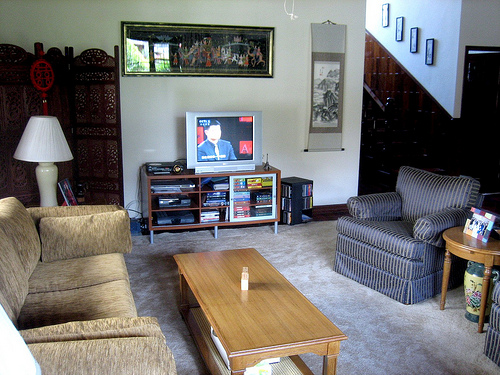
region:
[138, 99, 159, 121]
this is the wall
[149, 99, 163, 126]
the wall is clean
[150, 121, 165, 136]
the wall is white in color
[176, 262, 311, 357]
this is a table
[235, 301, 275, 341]
the table is brown in color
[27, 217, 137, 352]
this is a sofa set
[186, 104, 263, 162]
this is a TV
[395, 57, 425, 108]
this is a stair case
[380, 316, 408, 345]
this is the floor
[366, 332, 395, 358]
the floor is slippery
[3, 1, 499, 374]
A living room with tan carpeting and white walls.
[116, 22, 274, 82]
Oblong mirror on the wall.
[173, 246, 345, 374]
Brown wooden coffee table.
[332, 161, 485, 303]
Blue and white striped chair.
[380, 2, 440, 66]
Pictures on a wall along a stairway.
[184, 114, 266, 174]
Gray television set with a man on the screen.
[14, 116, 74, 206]
White lamp with a white shade.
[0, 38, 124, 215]
Brown room divider against the wall.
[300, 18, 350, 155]
A decorative scroll on the wall.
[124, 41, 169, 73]
Windows reflecting in the mirror.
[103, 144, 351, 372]
VIEW IS IN A SITTINGROOM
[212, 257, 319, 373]
the table is made of wood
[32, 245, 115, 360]
the copuches are woolen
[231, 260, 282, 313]
a bottle is on the table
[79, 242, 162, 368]
the couch is brown in color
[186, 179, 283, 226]
books are arranged in the shelf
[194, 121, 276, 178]
the tv is on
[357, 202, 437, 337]
the couch is back in color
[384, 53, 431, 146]
the stirs are wooden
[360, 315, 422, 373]
floor is lightbrown incolor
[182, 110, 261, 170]
The entire television, including stand.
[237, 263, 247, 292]
A lone salt shaker on a coffee table.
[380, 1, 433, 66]
A group of four pictures decorating the stairwell wall.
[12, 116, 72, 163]
A white lampshade attached to a lamp.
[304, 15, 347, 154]
The black and white tapestry hangs on the wall.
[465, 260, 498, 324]
A well decorated vase tucked under a round table.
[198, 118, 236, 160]
A gentleman who is appearing on television.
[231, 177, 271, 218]
A large selection of what appears to be VHS tapes behind a closed glass door.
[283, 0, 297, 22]
A piece of tied rope hanging from the ceiling.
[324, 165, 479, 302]
A pair of chairs, of which this one is mostly visible.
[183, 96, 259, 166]
grey frame on tv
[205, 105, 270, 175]
tv on brown table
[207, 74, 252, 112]
white wall behind tv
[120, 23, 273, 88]
mirror is above tv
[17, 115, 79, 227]
white lamp near wall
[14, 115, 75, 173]
white shade on lamp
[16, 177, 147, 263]
brown cushion on sofa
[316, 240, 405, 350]
carpet is light grey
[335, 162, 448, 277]
dark grey striped chair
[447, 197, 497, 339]
brown table near chair